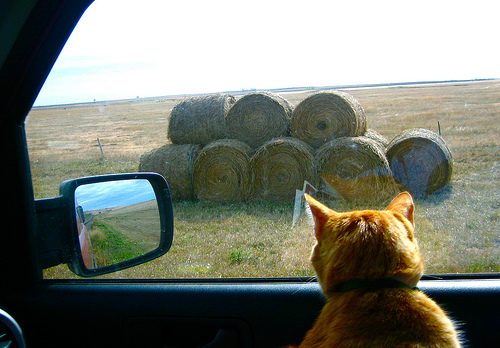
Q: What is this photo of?
A: A cat in a car.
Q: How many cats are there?
A: One.